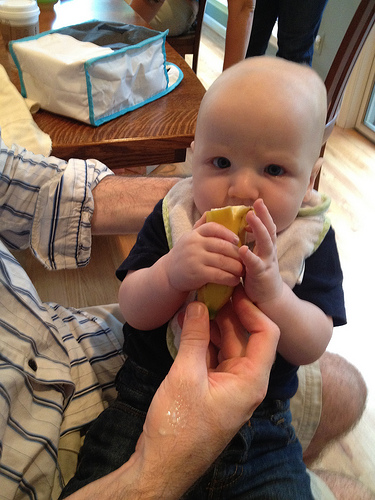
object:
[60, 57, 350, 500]
child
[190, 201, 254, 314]
banana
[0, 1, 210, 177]
table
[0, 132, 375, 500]
man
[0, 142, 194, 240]
arm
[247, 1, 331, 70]
pants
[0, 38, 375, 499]
floor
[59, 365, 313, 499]
jeans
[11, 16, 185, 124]
bag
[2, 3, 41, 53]
cup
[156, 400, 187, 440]
moisture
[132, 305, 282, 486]
hand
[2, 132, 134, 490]
shirt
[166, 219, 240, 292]
hand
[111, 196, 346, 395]
shirt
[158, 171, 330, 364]
bib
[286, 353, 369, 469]
legs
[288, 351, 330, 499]
shorts